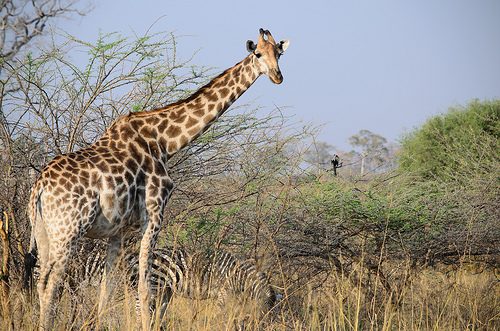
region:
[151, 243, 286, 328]
zebra hiding behind bush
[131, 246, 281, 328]
zebra grazing behind bush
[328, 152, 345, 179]
small black bird perched on limb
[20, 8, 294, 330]
tall giraffe standing next to brush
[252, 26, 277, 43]
zebra's tan and black horns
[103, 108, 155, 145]
hump on giraffes shoulders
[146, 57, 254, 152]
giraffe's long neck with spots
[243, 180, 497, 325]
tangle of limbs with green leaves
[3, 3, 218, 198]
tall limbs against a blue sky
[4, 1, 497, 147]
blue sky with grey haze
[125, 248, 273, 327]
A zebra eating the grass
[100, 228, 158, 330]
The front legs of the giraffe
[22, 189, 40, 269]
The tail of the giraffe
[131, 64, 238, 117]
The mane of the giraffe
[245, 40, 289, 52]
The ears of the giraffe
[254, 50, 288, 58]
The eyes of the giraffe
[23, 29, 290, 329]
A giraffe and a zebra in the field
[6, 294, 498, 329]
Grass beneath the animals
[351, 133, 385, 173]
A tree in the distance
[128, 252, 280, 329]
The zebra is below the giraffe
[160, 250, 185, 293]
a zebra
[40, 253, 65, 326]
back legs on the giraffe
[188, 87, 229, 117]
the neck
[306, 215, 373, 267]
tree branches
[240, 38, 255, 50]
the giraffes ear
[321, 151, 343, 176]
a bird on the branch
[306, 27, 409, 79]
the sky is clear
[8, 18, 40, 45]
tree branches on the tree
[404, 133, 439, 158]
a green bush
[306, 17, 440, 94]
a clear sky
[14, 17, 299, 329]
giraffe in the grass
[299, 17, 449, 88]
the sky is blue and clear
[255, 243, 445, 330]
the grass is tall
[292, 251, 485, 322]
the grass is dry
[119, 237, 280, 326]
the zebras by the giraffe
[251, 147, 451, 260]
small green bush behind the zebras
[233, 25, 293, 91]
head of the giraffe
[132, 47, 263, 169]
neck of the giraffe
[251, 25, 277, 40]
ossicones on the head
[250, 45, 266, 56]
eye of the giraffe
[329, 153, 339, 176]
a black bird sitting on a branch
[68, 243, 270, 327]
zebras hiding in the tall grass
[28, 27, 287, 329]
a tall giraffe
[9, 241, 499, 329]
tall yellow grass below the giraffe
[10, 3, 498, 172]
clear blue sky above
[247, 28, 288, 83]
the giraffe's head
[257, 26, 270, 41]
horns on the giraffe's head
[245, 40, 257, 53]
the giraffe's right ear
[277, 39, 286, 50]
the giraffe's left ear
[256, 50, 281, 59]
the tall giraffe's eyes